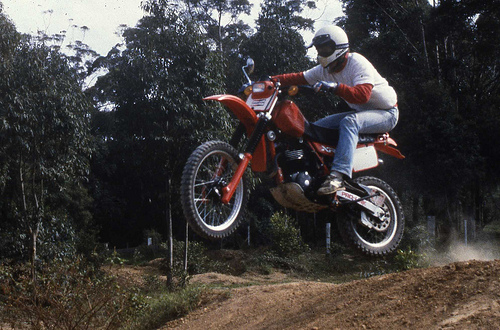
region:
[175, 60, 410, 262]
Red racing motorcycle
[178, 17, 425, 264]
man racing motorcycle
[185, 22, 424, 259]
man in white helmet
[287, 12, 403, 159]
Man in white shirt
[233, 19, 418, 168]
man in gloves racing motorcycle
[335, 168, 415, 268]
Back wheel of motorcycle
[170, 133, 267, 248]
Front wheel of motorcycle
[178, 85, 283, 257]
Wheel and front fender of motorcycle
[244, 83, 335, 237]
red motorcycle engine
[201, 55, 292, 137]
red motorcycle fender and light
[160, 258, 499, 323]
Dirt ramp in forest.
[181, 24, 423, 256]
Man riding red dirt bike.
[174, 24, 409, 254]
Man in air on dirt bike.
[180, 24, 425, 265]
Man jumping off ramp on dirt bike.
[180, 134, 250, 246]
Front tire of dirt bike.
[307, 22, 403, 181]
Man wearing light blue blue jeans.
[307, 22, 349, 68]
White helmet on man's head.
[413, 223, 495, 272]
Dust from man riding dirt bike.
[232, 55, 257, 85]
Silver mirror attached to dirt bike.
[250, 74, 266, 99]
Head light on front of dirt bike.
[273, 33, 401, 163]
person on the bike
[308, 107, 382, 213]
leg of the person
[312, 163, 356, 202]
foot of the person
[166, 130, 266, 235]
tire on the bike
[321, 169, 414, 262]
back tire of the bike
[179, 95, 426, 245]
red bike in the photo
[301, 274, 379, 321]
dirt under the biker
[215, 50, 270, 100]
mirror on side of bike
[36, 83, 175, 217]
trees next to the man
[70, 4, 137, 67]
sky above the trees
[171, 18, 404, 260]
a man on a motorcyle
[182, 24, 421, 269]
a man jumping a motorcyle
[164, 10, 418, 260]
an orange motocross motorcycle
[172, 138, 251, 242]
the front wheel of a motorycle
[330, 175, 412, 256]
the rear wheel of a motocyle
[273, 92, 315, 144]
the gas tank of a motocyle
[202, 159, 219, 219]
the spokes of a motocyle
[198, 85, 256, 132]
the fender of a motocyle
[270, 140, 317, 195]
the engine of a motocyle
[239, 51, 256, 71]
the mirror on a motorcyle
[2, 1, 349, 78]
light in daytime sky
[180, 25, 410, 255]
man sitting on motorbike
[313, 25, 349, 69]
white helmet on head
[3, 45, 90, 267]
leaves on tree braches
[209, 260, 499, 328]
hill of brown dirt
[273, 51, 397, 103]
red sleeves under white shirt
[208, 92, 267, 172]
red fender of motorbike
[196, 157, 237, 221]
spokes in bike tire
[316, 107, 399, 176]
blue jeans on legs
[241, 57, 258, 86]
side view mirror on bike